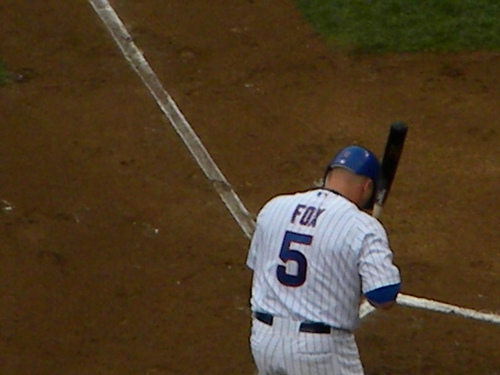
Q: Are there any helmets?
A: Yes, there is a helmet.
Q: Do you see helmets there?
A: Yes, there is a helmet.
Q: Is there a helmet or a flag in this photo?
A: Yes, there is a helmet.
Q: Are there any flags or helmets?
A: Yes, there is a helmet.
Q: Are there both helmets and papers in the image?
A: No, there is a helmet but no papers.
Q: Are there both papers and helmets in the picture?
A: No, there is a helmet but no papers.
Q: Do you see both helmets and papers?
A: No, there is a helmet but no papers.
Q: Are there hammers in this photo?
A: No, there are no hammers.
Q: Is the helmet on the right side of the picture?
A: Yes, the helmet is on the right of the image.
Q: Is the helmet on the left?
A: No, the helmet is on the right of the image.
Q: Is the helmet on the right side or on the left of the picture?
A: The helmet is on the right of the image.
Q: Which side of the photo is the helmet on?
A: The helmet is on the right of the image.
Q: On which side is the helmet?
A: The helmet is on the right of the image.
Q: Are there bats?
A: Yes, there is a bat.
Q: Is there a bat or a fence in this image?
A: Yes, there is a bat.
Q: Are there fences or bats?
A: Yes, there is a bat.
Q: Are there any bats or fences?
A: Yes, there is a bat.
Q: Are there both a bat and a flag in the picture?
A: No, there is a bat but no flags.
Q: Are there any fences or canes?
A: No, there are no fences or canes.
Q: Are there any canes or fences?
A: No, there are no fences or canes.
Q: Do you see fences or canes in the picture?
A: No, there are no fences or canes.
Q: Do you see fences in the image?
A: No, there are no fences.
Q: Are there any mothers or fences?
A: No, there are no fences or mothers.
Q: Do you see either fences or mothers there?
A: No, there are no fences or mothers.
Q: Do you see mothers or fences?
A: No, there are no fences or mothers.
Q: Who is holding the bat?
A: The batter is holding the bat.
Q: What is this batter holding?
A: The batter is holding the bat.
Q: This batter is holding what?
A: The batter is holding the bat.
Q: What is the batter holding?
A: The batter is holding the bat.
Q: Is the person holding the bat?
A: Yes, the batter is holding the bat.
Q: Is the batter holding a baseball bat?
A: No, the batter is holding the bat.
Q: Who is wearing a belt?
A: The batter is wearing a belt.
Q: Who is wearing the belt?
A: The batter is wearing a belt.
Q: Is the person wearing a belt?
A: Yes, the batter is wearing a belt.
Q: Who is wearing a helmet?
A: The batter is wearing a helmet.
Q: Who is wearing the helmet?
A: The batter is wearing a helmet.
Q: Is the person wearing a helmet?
A: Yes, the batter is wearing a helmet.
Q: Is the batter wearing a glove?
A: No, the batter is wearing a helmet.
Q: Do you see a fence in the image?
A: No, there are no fences.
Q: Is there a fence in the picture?
A: No, there are no fences.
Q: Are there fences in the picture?
A: No, there are no fences.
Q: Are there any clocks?
A: No, there are no clocks.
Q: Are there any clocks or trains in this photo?
A: No, there are no clocks or trains.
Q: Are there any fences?
A: No, there are no fences.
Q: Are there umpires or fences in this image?
A: No, there are no fences or umpires.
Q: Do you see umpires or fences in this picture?
A: No, there are no fences or umpires.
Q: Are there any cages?
A: No, there are no cages.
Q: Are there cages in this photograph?
A: No, there are no cages.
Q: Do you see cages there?
A: No, there are no cages.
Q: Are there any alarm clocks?
A: No, there are no alarm clocks.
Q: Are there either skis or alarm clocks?
A: No, there are no alarm clocks or skis.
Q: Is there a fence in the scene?
A: No, there are no fences.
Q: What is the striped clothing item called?
A: The clothing item is a uniform.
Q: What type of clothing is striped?
A: The clothing is a uniform.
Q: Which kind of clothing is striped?
A: The clothing is a uniform.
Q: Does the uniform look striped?
A: Yes, the uniform is striped.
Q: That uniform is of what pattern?
A: The uniform is striped.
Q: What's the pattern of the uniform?
A: The uniform is striped.